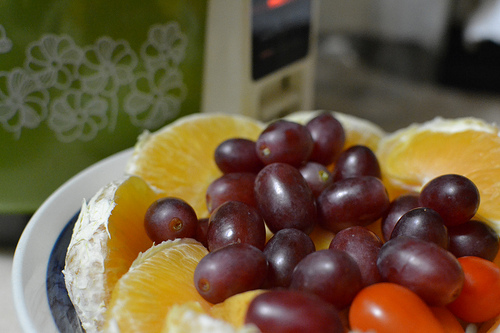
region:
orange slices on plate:
[83, 113, 482, 328]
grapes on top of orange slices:
[150, 121, 462, 319]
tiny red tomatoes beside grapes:
[345, 253, 499, 326]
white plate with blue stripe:
[18, 138, 268, 330]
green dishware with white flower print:
[1, 0, 206, 223]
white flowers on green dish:
[1, 25, 197, 155]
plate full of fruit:
[21, 109, 496, 332]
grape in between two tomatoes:
[355, 237, 498, 331]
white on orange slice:
[62, 168, 125, 322]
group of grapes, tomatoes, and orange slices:
[98, 101, 499, 332]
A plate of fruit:
[15, 94, 497, 331]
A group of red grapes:
[214, 136, 419, 246]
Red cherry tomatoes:
[359, 260, 499, 331]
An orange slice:
[76, 182, 152, 284]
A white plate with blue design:
[11, 188, 76, 331]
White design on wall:
[9, 30, 185, 126]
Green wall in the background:
[8, 140, 65, 176]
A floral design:
[26, 35, 87, 86]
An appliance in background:
[203, 2, 333, 110]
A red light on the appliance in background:
[256, 0, 315, 15]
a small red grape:
[146, 195, 194, 245]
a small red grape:
[194, 241, 267, 302]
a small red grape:
[209, 202, 264, 250]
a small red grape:
[247, 287, 339, 331]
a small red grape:
[294, 250, 362, 305]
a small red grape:
[257, 225, 313, 290]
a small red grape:
[253, 163, 315, 230]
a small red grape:
[204, 171, 257, 212]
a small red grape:
[215, 137, 262, 172]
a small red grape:
[257, 117, 312, 167]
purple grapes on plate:
[185, 90, 423, 297]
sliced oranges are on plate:
[47, 65, 263, 331]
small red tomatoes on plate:
[341, 243, 496, 328]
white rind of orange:
[81, 151, 119, 311]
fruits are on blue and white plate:
[27, 161, 482, 329]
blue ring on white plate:
[31, 183, 112, 328]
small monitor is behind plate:
[217, 0, 322, 105]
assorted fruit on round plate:
[70, 137, 412, 325]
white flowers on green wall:
[15, 26, 180, 152]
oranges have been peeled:
[80, 86, 308, 328]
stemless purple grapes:
[141, 114, 496, 328]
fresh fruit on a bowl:
[12, 106, 497, 331]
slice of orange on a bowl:
[64, 172, 159, 329]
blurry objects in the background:
[2, 2, 317, 246]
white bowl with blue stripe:
[13, 140, 136, 330]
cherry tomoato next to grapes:
[346, 283, 437, 332]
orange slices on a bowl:
[65, 110, 497, 332]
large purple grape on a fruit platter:
[254, 164, 317, 234]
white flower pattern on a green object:
[1, 18, 188, 140]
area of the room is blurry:
[310, 0, 497, 136]